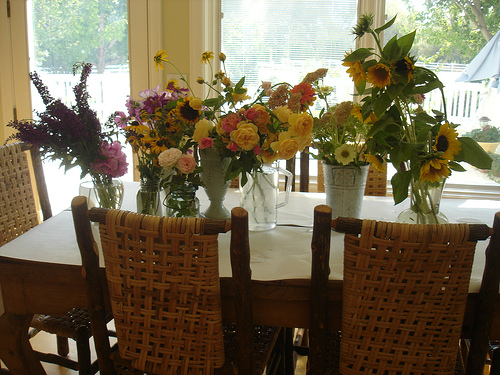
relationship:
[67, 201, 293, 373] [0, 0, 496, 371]
chair in room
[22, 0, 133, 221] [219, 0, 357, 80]
window showing outside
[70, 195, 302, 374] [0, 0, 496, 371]
chair in room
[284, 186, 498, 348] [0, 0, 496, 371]
chair in room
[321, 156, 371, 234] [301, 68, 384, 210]
vase has flowers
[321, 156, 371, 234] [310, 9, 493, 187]
vase has flowers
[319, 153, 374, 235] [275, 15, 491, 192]
vase has flowers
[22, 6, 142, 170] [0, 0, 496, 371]
window in room